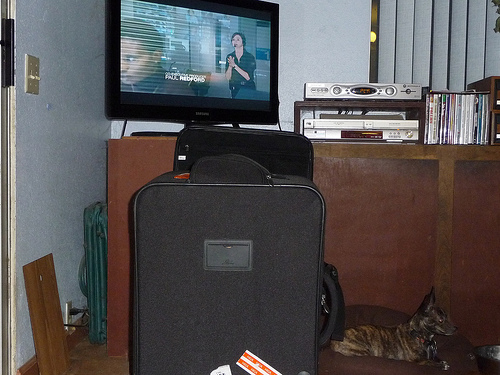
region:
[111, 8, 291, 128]
flatscreen tv thats on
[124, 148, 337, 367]
black upright suitcase in center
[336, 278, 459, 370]
small brown and black dog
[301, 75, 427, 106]
silver reciever for tv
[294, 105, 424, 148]
silver sound system reciever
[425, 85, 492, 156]
small collection of dvd's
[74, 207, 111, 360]
green bag folded by wall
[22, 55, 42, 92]
beige double light switch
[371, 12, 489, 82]
white venetian blinds on window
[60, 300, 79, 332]
white outlet with plug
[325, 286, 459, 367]
A small brown dog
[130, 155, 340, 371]
a soft black suitcase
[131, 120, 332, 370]
Two soft black suitcases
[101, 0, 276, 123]
A black flatscreen television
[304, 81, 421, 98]
A cable TV receiver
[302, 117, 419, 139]
A silver stereo receiver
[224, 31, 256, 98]
A woman on television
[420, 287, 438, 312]
A dog's right ear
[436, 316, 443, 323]
A dog's right eye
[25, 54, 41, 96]
A light switch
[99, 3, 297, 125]
the television is on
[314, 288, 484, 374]
the dog on the cushion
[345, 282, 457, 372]
the dog is brown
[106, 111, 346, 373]
the suit case is black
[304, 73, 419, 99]
the cable box by the television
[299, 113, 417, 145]
dvd player below the cable box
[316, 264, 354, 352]
handle on the suitcase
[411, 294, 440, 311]
ears of the dog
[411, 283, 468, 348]
head of the dog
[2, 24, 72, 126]
Light switch on the wall.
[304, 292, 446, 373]
Dark dog on the floor.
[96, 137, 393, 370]
Suitcase on the floor.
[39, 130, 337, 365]
Black suitcase on the floor.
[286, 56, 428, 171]
DVR on the desk.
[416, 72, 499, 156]
DVDs on the desk.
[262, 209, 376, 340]
Handle on the suitcase.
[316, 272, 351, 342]
Zipper on the suitcase.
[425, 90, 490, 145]
Small stack of DVD's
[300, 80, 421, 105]
Silver cable box with black center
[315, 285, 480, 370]
Brown dog laying on a bean bag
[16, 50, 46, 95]
Light switch flipped down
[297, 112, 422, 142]
DVD and VCR player in one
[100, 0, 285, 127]
TV that is turned on showing a TV show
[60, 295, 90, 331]
Black plug that is plugged into outlet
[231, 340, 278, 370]
Orange and white tape on suitcase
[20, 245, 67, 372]
Wood balancing against the wall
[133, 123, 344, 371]
Grey suitcase standing up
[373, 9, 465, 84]
blinds on the window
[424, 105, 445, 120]
movie on the desk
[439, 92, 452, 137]
movie on the desk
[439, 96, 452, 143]
movie on the desk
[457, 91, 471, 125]
movie on the desk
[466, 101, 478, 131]
movie on the desk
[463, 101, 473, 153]
movie on the desk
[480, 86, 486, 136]
movie on the desk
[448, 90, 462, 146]
movie on the desk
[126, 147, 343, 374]
suitcase is black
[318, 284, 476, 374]
dog is laying down on brown dog bed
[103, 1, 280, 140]
flatscreen TV is on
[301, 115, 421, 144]
DVD player is silver